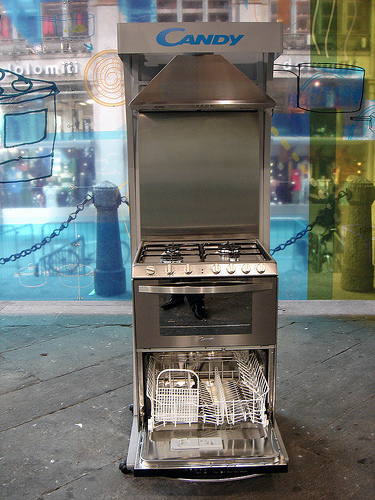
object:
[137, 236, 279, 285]
stove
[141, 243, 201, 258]
burner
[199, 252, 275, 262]
burner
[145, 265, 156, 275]
control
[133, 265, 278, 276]
panel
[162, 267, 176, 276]
control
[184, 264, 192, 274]
control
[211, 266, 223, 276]
control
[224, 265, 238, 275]
control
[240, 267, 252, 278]
control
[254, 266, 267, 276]
control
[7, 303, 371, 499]
floor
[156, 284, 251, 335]
window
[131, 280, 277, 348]
door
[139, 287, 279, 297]
handle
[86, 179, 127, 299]
post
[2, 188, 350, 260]
chain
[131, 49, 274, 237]
hood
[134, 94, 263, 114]
vent